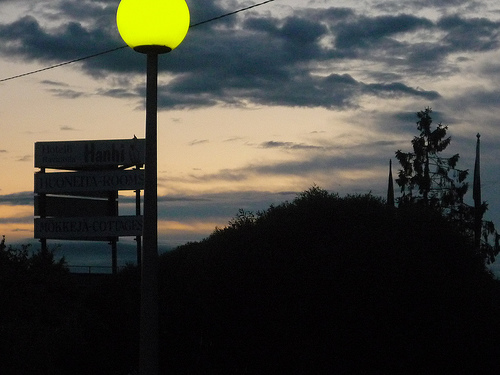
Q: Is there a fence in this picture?
A: No, there are no fences.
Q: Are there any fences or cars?
A: No, there are no fences or cars.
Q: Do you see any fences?
A: No, there are no fences.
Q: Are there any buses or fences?
A: No, there are no fences or buses.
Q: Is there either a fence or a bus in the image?
A: No, there are no fences or buses.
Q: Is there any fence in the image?
A: No, there are no fences.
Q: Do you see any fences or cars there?
A: No, there are no fences or cars.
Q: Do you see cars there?
A: No, there are no cars.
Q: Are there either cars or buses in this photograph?
A: No, there are no cars or buses.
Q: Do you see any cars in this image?
A: No, there are no cars.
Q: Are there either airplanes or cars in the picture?
A: No, there are no cars or airplanes.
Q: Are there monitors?
A: No, there are no monitors.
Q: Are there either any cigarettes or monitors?
A: No, there are no monitors or cigarettes.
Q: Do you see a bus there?
A: No, there are no buses.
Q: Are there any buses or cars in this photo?
A: No, there are no buses or cars.